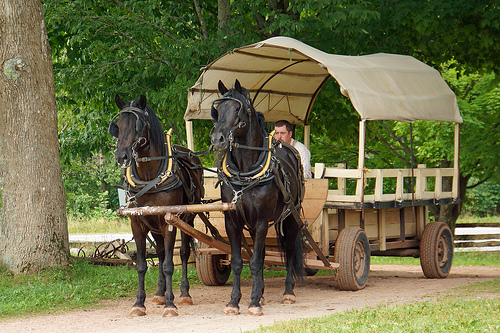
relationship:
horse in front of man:
[110, 94, 202, 314] [270, 114, 308, 177]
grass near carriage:
[284, 278, 500, 332] [156, 35, 467, 292]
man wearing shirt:
[266, 117, 313, 184] [289, 137, 311, 178]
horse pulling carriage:
[110, 94, 202, 314] [184, 37, 464, 293]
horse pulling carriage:
[208, 78, 306, 313] [184, 37, 464, 293]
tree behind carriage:
[72, 8, 500, 124] [184, 37, 461, 287]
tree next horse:
[1, 0, 76, 272] [105, 92, 205, 319]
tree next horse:
[1, 0, 76, 272] [208, 78, 306, 313]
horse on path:
[110, 94, 202, 314] [6, 261, 497, 327]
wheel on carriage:
[332, 221, 374, 292] [184, 37, 464, 293]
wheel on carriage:
[420, 220, 454, 278] [184, 37, 464, 293]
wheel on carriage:
[194, 244, 226, 287] [184, 37, 464, 293]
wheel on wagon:
[194, 244, 226, 287] [192, 35, 462, 287]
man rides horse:
[266, 117, 313, 184] [102, 76, 209, 322]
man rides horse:
[266, 117, 313, 184] [192, 73, 312, 319]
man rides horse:
[266, 117, 313, 184] [208, 78, 306, 313]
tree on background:
[72, 8, 199, 99] [12, 7, 498, 119]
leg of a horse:
[245, 217, 268, 319] [203, 74, 311, 320]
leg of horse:
[245, 217, 268, 319] [166, 65, 331, 315]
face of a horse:
[114, 118, 140, 165] [105, 92, 205, 319]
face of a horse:
[208, 100, 242, 150] [208, 78, 306, 313]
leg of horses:
[225, 228, 242, 315] [107, 70, 307, 317]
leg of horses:
[130, 220, 150, 310] [107, 70, 307, 317]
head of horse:
[209, 78, 253, 151] [208, 78, 306, 313]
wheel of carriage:
[332, 221, 374, 292] [323, 38, 470, 274]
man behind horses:
[266, 114, 313, 184] [89, 70, 312, 322]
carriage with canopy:
[184, 37, 461, 287] [184, 35, 461, 123]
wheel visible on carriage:
[194, 244, 226, 287] [177, 22, 471, 219]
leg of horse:
[281, 236, 297, 303] [208, 78, 306, 313]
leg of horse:
[225, 228, 242, 315] [208, 78, 306, 313]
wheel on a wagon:
[323, 189, 423, 326] [173, 29, 463, 293]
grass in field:
[242, 277, 499, 331] [24, 253, 472, 328]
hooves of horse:
[221, 291, 300, 315] [208, 78, 306, 313]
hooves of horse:
[128, 292, 195, 317] [105, 92, 205, 319]